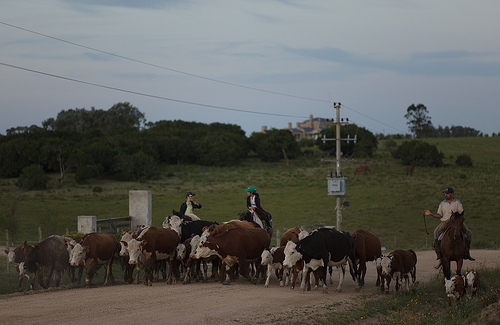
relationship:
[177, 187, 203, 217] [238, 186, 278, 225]
person on a horse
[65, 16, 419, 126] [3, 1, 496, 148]
clouds in sky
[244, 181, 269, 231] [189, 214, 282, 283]
person on horse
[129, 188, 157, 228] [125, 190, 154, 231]
gray cement on column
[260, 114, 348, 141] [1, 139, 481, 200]
home on hilltop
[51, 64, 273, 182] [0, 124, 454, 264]
tree on hilltop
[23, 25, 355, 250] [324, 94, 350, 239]
electric lines connected to pole